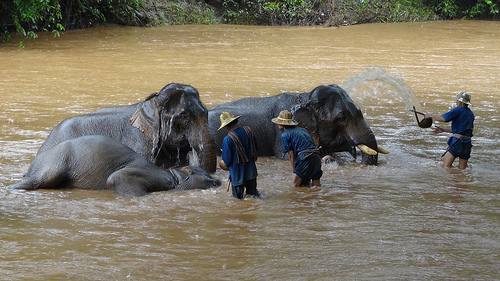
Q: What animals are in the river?
A: Elephants.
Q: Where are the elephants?
A: In the river.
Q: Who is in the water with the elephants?
A: Three men.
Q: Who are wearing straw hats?
A: Three men.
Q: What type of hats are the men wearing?
A: Straw.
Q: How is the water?
A: Muddy.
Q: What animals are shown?
A: Elephants.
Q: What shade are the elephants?
A: Gray.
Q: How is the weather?
A: Clear.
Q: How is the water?
A: Calm.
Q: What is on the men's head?
A: Hats.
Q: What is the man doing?
A: Bathing the elephants.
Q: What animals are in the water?
A: Elephants.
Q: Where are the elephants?
A: In the river.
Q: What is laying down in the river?
A: Elephant.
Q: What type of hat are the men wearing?
A: Straw.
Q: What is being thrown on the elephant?
A: Water.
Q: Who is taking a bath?
A: The elephants.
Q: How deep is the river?
A: Shallow.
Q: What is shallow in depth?
A: The river.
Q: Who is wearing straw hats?
A: Three men.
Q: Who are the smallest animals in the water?
A: Three men.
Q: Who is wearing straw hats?
A: Three men.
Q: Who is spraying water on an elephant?
A: Man on right.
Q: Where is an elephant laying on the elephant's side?
A: Left front.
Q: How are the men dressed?
A: Blue shirts and pants or shorts with hats.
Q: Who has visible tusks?
A: Elephant on right.